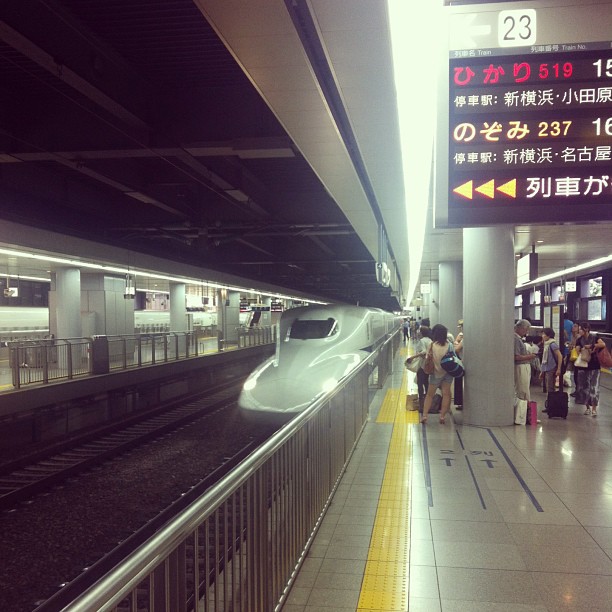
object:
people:
[400, 316, 606, 423]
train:
[237, 304, 412, 433]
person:
[419, 323, 453, 424]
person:
[539, 327, 563, 413]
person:
[575, 319, 607, 416]